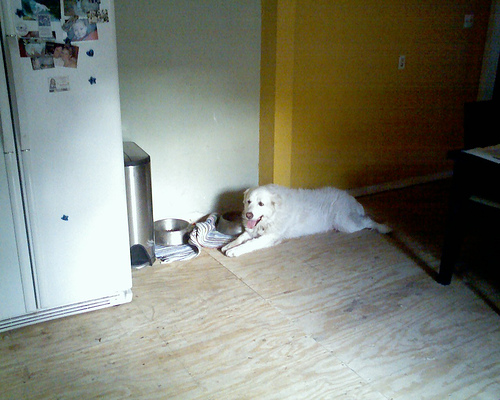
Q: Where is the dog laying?
A: Floor.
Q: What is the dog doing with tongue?
A: Panting.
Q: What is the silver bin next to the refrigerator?
A: Trash can.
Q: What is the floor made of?
A: Wood.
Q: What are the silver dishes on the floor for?
A: Dog's food and water.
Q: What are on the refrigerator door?
A: Pictures.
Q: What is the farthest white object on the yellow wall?
A: Light switch.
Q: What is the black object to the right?
A: Table.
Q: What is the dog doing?
A: Laying down.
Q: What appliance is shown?
A: A refrigerator.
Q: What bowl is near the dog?
A: Food bowl.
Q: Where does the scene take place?
A: In a kitchen.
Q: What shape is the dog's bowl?
A: Round.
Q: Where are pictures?
A: On the fridge.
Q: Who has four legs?
A: The dog.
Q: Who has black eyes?
A: A dog.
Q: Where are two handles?
A: On the fridge.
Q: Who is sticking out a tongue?
A: The dog.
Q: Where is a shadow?
A: On the wall.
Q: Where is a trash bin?
A: Next to the fridge.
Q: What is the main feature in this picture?
A: A dog.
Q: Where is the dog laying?
A: By his food bowls.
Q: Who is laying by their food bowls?
A: The dog.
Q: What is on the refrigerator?
A: Pictures.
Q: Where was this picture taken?
A: Inside a home.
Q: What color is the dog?
A: White.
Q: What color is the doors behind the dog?
A: Yellow.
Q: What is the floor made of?
A: Wood.